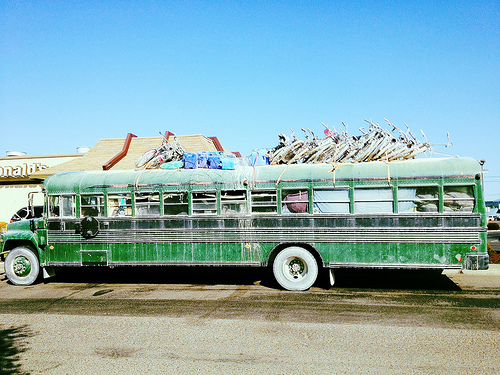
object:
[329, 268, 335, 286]
flap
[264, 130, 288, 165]
bicycle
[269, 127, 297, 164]
bicycle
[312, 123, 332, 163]
bicycle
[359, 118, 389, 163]
bicycle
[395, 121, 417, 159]
bicycle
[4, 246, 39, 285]
tire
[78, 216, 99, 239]
sign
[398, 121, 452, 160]
bicycles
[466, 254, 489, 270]
back bumper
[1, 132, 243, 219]
restaurant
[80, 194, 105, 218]
passenger window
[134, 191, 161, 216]
passenger window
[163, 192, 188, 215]
passenger window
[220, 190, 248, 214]
passenger window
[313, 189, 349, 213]
passenger window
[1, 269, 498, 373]
street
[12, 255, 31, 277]
green rim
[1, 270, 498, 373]
road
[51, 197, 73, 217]
window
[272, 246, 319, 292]
snowboard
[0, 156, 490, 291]
bus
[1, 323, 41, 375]
shadow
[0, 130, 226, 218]
mcdonald's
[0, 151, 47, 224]
building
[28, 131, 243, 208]
building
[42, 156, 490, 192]
roof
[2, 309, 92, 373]
ground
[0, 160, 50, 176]
letters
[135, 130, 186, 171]
bicycles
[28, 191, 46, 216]
side window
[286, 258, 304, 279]
center